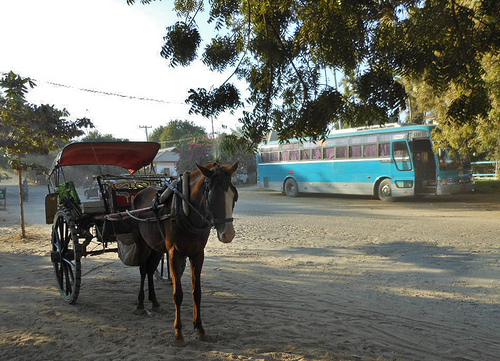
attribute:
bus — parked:
[253, 123, 437, 202]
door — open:
[390, 138, 415, 198]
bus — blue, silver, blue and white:
[256, 121, 476, 201]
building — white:
[138, 149, 184, 182]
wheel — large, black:
[56, 208, 87, 310]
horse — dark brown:
[122, 164, 242, 349]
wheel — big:
[24, 178, 102, 358]